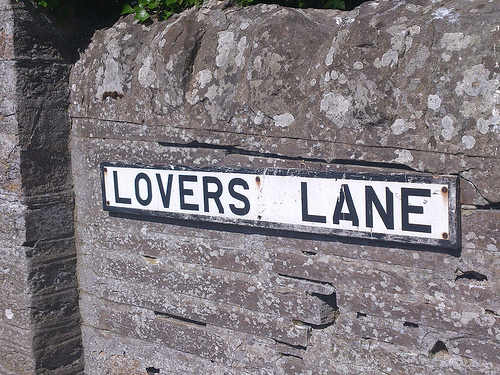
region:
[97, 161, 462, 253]
A black and white sign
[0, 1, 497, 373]
A tall limestone wall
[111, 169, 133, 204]
A black letter L on white sign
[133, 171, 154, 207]
A black letter O on a white backround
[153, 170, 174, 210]
A black letter V on a white backround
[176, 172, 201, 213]
A black letter E on a white backround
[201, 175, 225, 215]
A black letter R on a white backround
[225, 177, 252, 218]
A black letter S on white backround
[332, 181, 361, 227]
A black letter A on a white backround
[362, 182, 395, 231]
A black letter N on white backround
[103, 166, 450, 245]
black and white sign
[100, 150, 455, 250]
sign with white background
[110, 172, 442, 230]
black lettering on white sign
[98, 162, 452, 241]
bolts holding sign to rock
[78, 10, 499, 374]
stone wall sign is attaching to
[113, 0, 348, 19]
trees behind rock wall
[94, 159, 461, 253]
black edges of white sign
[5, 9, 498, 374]
two stone walls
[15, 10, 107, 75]
shadow on top of stone wall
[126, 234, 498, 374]
cracks in the stone wall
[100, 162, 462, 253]
A sign on the wall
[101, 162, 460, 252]
The sign is white and black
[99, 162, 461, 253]
The sign is rectangular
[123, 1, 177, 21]
Leaves behind the wall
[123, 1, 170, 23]
The leaves are green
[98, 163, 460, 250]
A sign for Lovers Lane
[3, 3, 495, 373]
A stone wall behind the sign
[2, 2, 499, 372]
The stone wall is damaged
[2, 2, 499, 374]
The stone wall is gray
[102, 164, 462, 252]
The paint on the sign is chipped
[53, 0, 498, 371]
The sign is attached to a large rock.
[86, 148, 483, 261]
The sign is black and white.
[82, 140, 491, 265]
The sign is rectangular.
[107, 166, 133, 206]
The letter is black.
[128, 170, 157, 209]
The letter is black.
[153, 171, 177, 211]
The letter is black.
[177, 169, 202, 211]
The letter is black.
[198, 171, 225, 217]
The letter is black.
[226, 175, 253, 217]
The letter is black.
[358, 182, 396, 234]
The letter is black.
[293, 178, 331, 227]
The letter is black.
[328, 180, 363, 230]
The letter is black.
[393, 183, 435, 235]
The letter is black.